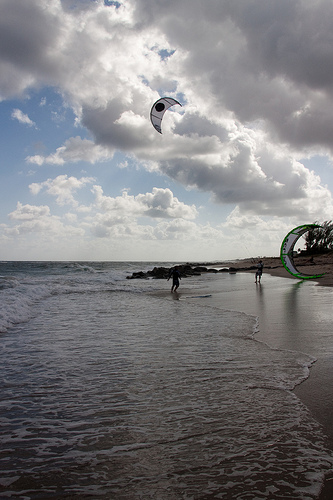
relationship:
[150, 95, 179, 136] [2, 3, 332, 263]
parasail in sky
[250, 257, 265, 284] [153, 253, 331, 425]
person standing on beach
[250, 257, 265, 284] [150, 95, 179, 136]
person flying parasail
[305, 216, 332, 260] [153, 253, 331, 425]
tree on beach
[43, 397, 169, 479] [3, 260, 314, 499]
sea foam on water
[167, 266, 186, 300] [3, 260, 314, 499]
person standing in water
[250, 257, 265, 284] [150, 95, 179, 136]
person holding parasail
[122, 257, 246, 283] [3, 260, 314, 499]
rocks in water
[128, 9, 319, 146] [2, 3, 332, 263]
cloud in sky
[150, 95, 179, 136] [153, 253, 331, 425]
parasail on beach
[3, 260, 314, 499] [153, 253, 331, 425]
water in front of beach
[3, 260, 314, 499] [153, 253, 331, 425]
water on beach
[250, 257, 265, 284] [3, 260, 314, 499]
person standing in water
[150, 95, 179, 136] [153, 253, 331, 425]
parasail laying on beach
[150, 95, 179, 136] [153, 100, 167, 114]
parasail with circle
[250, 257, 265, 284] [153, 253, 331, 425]
person on beach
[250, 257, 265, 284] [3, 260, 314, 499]
person standing near water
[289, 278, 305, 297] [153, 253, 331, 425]
shadow on beach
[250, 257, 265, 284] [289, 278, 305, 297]
person casting shadow